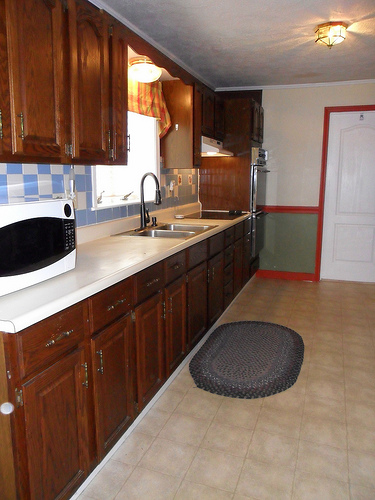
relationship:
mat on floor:
[188, 313, 305, 400] [220, 245, 374, 498]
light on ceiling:
[309, 19, 350, 52] [84, 2, 372, 98]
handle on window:
[96, 188, 106, 205] [91, 112, 161, 210]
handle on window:
[121, 188, 134, 201] [91, 112, 161, 210]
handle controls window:
[96, 188, 106, 205] [91, 112, 161, 210]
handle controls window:
[121, 188, 134, 201] [91, 112, 161, 210]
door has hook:
[320, 107, 372, 283] [358, 114, 366, 121]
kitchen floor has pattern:
[161, 406, 317, 478] [185, 404, 335, 486]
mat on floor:
[188, 313, 305, 400] [256, 274, 371, 395]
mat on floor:
[188, 313, 305, 400] [107, 274, 372, 498]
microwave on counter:
[0, 193, 78, 293] [89, 204, 206, 296]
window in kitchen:
[97, 112, 162, 206] [3, 0, 373, 497]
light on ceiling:
[309, 19, 350, 52] [91, 0, 373, 92]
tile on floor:
[282, 287, 328, 309] [83, 272, 374, 499]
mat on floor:
[188, 313, 305, 400] [83, 272, 374, 499]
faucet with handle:
[138, 169, 159, 227] [141, 211, 151, 222]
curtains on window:
[124, 74, 179, 124] [116, 86, 172, 193]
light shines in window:
[93, 110, 159, 201] [91, 112, 161, 210]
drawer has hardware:
[163, 252, 189, 283] [207, 269, 215, 281]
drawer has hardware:
[87, 276, 133, 334] [160, 296, 175, 316]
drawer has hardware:
[136, 262, 164, 305] [80, 348, 104, 388]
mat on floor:
[188, 313, 308, 400] [249, 281, 373, 496]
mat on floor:
[188, 313, 305, 400] [160, 418, 269, 498]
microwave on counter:
[0, 198, 78, 294] [0, 229, 180, 343]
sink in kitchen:
[138, 212, 218, 245] [17, 9, 367, 366]